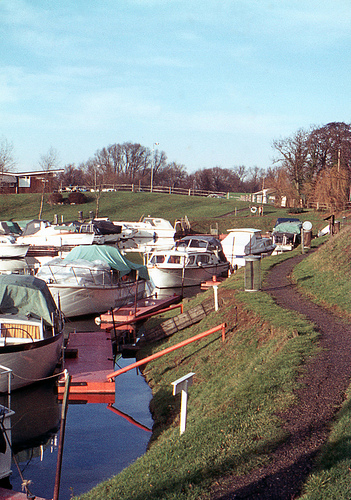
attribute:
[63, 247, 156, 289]
cover — green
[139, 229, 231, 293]
boat — small, white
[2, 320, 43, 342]
curtains — yellow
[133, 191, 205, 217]
grass — patchy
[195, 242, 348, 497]
street — black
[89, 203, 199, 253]
boat — white, small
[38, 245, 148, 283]
covering — green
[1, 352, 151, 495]
water — reflective, blue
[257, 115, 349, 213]
trees — leafless, brown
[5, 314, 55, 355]
curtain — yellow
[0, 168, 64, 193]
shack — little, brown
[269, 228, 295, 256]
boat — white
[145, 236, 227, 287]
boat — white, small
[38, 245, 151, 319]
boat — white, small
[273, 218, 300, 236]
cover — blue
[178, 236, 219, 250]
cover — blue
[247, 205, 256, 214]
sign — white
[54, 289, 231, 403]
dock — red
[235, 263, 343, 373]
path — curvy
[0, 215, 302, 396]
boats — different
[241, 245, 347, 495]
path — curving, dirt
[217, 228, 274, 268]
white boat — small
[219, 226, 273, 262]
boat — small, white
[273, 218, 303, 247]
boat — small, white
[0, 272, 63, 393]
boat — small, white